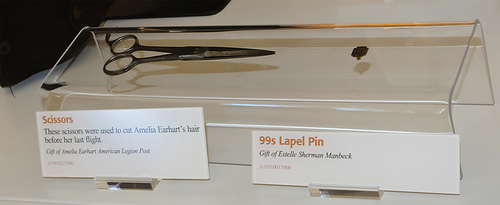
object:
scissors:
[103, 30, 276, 76]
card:
[35, 106, 209, 179]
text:
[43, 115, 73, 123]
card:
[252, 131, 461, 195]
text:
[43, 127, 61, 134]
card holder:
[94, 176, 162, 190]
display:
[39, 19, 496, 179]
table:
[0, 0, 500, 205]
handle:
[105, 33, 139, 55]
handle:
[103, 52, 137, 75]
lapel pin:
[351, 46, 369, 60]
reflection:
[107, 50, 280, 93]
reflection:
[354, 61, 372, 74]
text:
[308, 136, 324, 147]